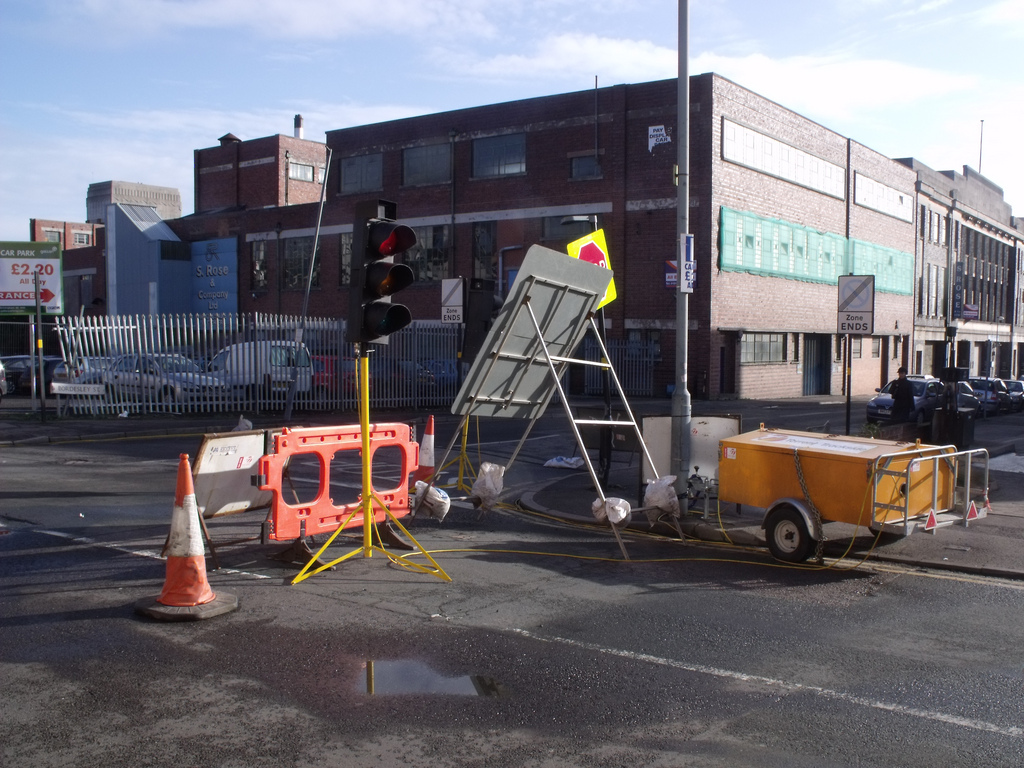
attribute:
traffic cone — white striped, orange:
[153, 452, 218, 612]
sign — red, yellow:
[570, 227, 615, 308]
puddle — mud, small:
[365, 646, 487, 694]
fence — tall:
[49, 311, 460, 413]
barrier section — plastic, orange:
[259, 424, 412, 542]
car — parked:
[875, 377, 959, 422]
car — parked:
[944, 379, 979, 412]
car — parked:
[978, 382, 1007, 411]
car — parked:
[1009, 380, 1022, 412]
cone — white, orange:
[124, 455, 242, 629]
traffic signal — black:
[352, 191, 414, 363]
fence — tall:
[43, 313, 329, 421]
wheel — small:
[751, 497, 821, 565]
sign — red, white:
[0, 257, 62, 309]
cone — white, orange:
[416, 412, 440, 482]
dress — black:
[886, 373, 923, 436]